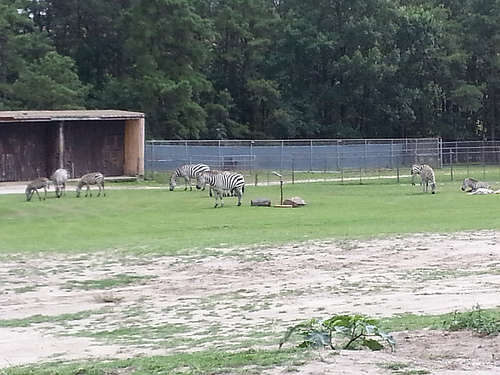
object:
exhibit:
[0, 139, 500, 373]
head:
[196, 173, 206, 189]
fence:
[146, 138, 500, 185]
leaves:
[448, 303, 499, 337]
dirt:
[0, 229, 500, 375]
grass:
[0, 162, 500, 375]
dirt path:
[0, 174, 415, 195]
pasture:
[1, 162, 500, 375]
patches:
[0, 229, 500, 375]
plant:
[278, 314, 395, 352]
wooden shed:
[1, 110, 146, 182]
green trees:
[0, 0, 500, 146]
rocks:
[283, 197, 306, 207]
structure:
[0, 109, 145, 183]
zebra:
[25, 163, 500, 208]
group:
[25, 163, 500, 208]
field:
[2, 193, 497, 245]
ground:
[3, 213, 322, 371]